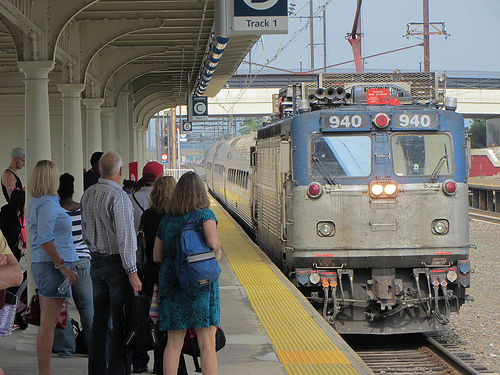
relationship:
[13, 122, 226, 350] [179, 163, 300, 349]
people at platform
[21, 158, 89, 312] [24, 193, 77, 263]
lady wearing shirt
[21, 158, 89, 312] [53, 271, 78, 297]
lady with bottle